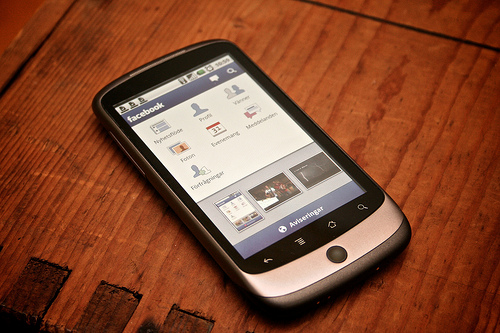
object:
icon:
[184, 96, 213, 123]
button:
[248, 245, 289, 274]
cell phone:
[81, 31, 433, 331]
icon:
[221, 82, 248, 103]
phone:
[84, 29, 427, 330]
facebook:
[133, 76, 340, 239]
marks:
[1, 245, 217, 330]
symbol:
[174, 62, 198, 86]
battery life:
[192, 65, 208, 81]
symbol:
[188, 62, 213, 80]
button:
[321, 240, 353, 269]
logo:
[126, 96, 171, 126]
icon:
[202, 113, 227, 140]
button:
[322, 213, 343, 236]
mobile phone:
[82, 27, 422, 325]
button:
[352, 189, 379, 216]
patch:
[46, 165, 116, 232]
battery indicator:
[195, 68, 208, 74]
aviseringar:
[290, 204, 322, 228]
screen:
[113, 53, 365, 259]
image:
[111, 54, 364, 258]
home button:
[326, 218, 336, 229]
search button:
[357, 200, 369, 212]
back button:
[262, 254, 275, 265]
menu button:
[291, 233, 308, 246]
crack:
[303, 1, 497, 51]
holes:
[308, 290, 331, 307]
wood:
[0, 1, 499, 331]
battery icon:
[192, 64, 210, 80]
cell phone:
[88, 69, 420, 265]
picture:
[248, 168, 304, 210]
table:
[0, 0, 499, 331]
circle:
[324, 242, 349, 267]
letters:
[124, 99, 165, 123]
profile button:
[188, 98, 210, 120]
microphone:
[321, 241, 348, 265]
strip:
[17, 239, 135, 330]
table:
[45, 165, 183, 319]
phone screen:
[108, 41, 387, 274]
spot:
[31, 2, 121, 95]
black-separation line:
[323, 2, 465, 45]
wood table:
[316, 38, 475, 136]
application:
[204, 115, 237, 146]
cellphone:
[116, 30, 386, 320]